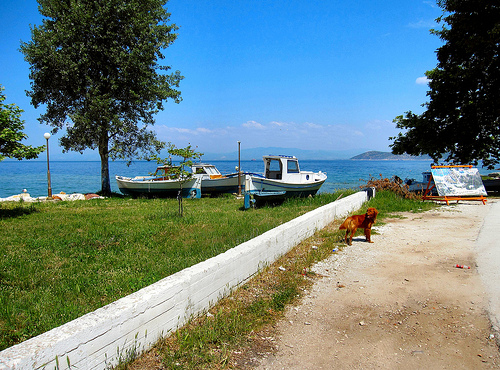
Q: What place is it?
A: It is a road.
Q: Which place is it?
A: It is a road.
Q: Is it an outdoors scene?
A: Yes, it is outdoors.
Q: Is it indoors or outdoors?
A: It is outdoors.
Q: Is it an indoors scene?
A: No, it is outdoors.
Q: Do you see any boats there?
A: Yes, there is a boat.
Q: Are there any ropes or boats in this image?
A: Yes, there is a boat.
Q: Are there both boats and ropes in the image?
A: No, there is a boat but no ropes.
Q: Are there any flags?
A: No, there are no flags.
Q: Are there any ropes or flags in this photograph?
A: No, there are no flags or ropes.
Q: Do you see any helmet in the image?
A: No, there are no helmets.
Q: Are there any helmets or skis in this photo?
A: No, there are no helmets or skis.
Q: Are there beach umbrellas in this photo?
A: No, there are no beach umbrellas.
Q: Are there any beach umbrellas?
A: No, there are no beach umbrellas.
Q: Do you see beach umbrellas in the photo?
A: No, there are no beach umbrellas.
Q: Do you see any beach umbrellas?
A: No, there are no beach umbrellas.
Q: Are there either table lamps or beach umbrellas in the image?
A: No, there are no beach umbrellas or table lamps.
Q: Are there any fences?
A: No, there are no fences.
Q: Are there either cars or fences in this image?
A: No, there are no fences or cars.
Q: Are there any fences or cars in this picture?
A: No, there are no fences or cars.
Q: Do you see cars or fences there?
A: No, there are no fences or cars.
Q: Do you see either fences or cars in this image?
A: No, there are no fences or cars.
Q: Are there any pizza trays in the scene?
A: No, there are no pizza trays.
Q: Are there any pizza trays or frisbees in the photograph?
A: No, there are no pizza trays or frisbees.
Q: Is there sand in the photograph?
A: Yes, there is sand.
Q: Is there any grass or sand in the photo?
A: Yes, there is sand.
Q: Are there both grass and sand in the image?
A: Yes, there are both sand and grass.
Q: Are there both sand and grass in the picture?
A: Yes, there are both sand and grass.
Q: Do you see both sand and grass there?
A: Yes, there are both sand and grass.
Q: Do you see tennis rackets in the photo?
A: No, there are no tennis rackets.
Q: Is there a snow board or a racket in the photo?
A: No, there are no rackets or snowboards.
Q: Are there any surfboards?
A: No, there are no surfboards.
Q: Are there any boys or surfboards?
A: No, there are no surfboards or boys.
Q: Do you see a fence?
A: No, there are no fences.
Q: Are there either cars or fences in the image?
A: No, there are no fences or cars.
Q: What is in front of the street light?
A: The tree is in front of the street light.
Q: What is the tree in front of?
A: The tree is in front of the street lamp.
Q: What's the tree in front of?
A: The tree is in front of the street lamp.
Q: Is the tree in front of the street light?
A: Yes, the tree is in front of the street light.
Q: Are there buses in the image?
A: No, there are no buses.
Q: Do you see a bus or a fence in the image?
A: No, there are no buses or fences.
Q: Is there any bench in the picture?
A: No, there are no benches.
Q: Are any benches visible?
A: No, there are no benches.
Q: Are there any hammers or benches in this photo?
A: No, there are no benches or hammers.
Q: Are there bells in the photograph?
A: No, there are no bells.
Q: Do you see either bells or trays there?
A: No, there are no bells or trays.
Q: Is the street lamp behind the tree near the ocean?
A: Yes, the street lamp is behind the tree.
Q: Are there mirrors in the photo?
A: No, there are no mirrors.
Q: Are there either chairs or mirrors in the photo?
A: No, there are no mirrors or chairs.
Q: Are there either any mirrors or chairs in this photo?
A: No, there are no mirrors or chairs.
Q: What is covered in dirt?
A: The floor is covered in dirt.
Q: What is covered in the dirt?
A: The floor is covered in dirt.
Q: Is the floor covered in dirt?
A: Yes, the floor is covered in dirt.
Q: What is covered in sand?
A: The floor is covered in sand.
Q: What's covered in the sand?
A: The floor is covered in sand.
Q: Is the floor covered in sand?
A: Yes, the floor is covered in sand.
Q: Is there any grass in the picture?
A: Yes, there is grass.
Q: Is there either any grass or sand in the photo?
A: Yes, there is grass.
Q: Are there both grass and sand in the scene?
A: Yes, there are both grass and sand.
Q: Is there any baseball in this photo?
A: No, there are no baseballs.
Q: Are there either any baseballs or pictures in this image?
A: No, there are no baseballs or pictures.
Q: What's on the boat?
A: The grass is on the boat.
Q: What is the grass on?
A: The grass is on the boat.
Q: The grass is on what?
A: The grass is on the boat.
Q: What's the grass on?
A: The grass is on the boat.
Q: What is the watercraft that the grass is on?
A: The watercraft is a boat.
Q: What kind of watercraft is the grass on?
A: The grass is on the boat.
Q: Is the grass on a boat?
A: Yes, the grass is on a boat.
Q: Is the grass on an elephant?
A: No, the grass is on a boat.